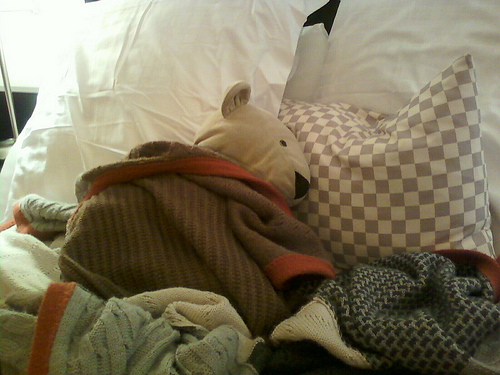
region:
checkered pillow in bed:
[283, 51, 490, 252]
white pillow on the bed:
[60, 0, 304, 116]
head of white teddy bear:
[205, 80, 306, 197]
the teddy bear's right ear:
[217, 79, 272, 117]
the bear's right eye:
[273, 128, 289, 154]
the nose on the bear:
[295, 148, 310, 201]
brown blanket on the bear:
[63, 144, 316, 318]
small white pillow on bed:
[318, 3, 498, 132]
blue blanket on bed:
[65, 293, 241, 370]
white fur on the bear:
[202, 114, 266, 157]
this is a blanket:
[14, 242, 37, 278]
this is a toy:
[203, 84, 307, 211]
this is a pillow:
[360, 125, 458, 212]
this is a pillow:
[111, 15, 191, 110]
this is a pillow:
[355, 41, 395, 76]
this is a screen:
[17, 90, 27, 116]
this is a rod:
[4, 82, 16, 121]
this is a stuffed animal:
[126, 41, 311, 207]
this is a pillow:
[311, 32, 496, 253]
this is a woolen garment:
[335, 244, 487, 373]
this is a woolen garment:
[86, 138, 234, 266]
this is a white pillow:
[101, 5, 298, 81]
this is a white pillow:
[337, 13, 432, 76]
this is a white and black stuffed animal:
[195, 80, 340, 215]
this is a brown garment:
[108, 192, 256, 287]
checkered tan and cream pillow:
[281, 51, 498, 251]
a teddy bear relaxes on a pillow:
[192, 81, 311, 208]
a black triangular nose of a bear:
[286, 166, 313, 203]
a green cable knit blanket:
[22, 282, 244, 374]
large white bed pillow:
[0, 0, 325, 208]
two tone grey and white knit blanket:
[266, 247, 497, 373]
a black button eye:
[278, 129, 289, 152]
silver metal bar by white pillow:
[1, 37, 18, 147]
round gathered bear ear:
[218, 80, 253, 115]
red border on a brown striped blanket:
[72, 151, 287, 194]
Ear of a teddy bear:
[216, 78, 253, 118]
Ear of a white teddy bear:
[218, 78, 255, 120]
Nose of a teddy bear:
[292, 169, 313, 201]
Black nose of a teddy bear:
[287, 168, 314, 205]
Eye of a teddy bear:
[276, 135, 290, 152]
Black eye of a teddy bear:
[276, 135, 291, 150]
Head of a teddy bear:
[198, 68, 326, 210]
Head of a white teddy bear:
[191, 76, 318, 216]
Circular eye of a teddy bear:
[277, 135, 289, 153]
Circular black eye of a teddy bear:
[277, 138, 291, 150]